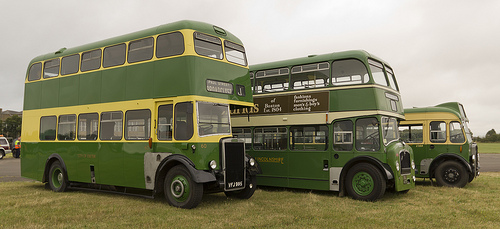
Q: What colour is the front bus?
A: Green and yellow.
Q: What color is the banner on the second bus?
A: Brown.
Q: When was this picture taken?
A: During the day.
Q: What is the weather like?
A: Cloudy.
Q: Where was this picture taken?
A: A parking lot.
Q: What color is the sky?
A: Gray.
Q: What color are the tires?
A: Black.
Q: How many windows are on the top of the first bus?
A: Nine.